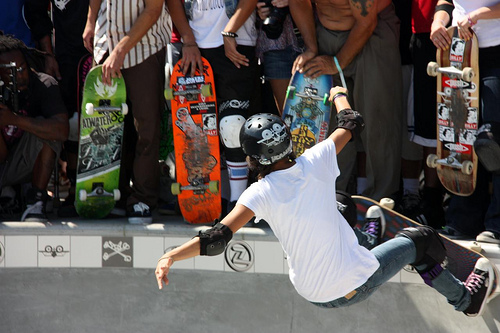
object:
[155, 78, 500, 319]
skateboarder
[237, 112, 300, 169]
helmet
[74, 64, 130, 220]
five skateboards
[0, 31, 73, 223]
man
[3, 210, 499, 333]
ground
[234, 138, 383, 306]
white shirt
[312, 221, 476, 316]
jeans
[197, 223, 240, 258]
elbow pad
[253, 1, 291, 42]
camera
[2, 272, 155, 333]
shadows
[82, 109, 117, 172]
graphic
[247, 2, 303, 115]
person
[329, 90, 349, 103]
wristband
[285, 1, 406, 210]
person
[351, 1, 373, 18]
tattoo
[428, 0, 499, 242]
person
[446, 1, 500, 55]
white shirt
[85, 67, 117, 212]
green bottom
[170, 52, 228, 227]
skateboard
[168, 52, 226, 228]
orange bottom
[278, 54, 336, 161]
skateboard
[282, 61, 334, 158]
blue bottom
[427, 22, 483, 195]
skateboard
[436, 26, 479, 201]
tan bottom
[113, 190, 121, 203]
wheels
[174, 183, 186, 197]
yellow wheels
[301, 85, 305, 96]
green wheels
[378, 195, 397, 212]
wheel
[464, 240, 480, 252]
wheel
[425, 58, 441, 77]
skateboard wheel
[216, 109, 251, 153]
knee pad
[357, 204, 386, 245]
shoe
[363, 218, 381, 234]
purple laces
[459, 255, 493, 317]
shoe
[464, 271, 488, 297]
pink laces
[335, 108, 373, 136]
elbow pad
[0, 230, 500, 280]
top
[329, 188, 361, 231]
knee pad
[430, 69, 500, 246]
jeans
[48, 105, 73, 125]
bicep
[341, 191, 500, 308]
skateboard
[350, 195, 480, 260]
edge